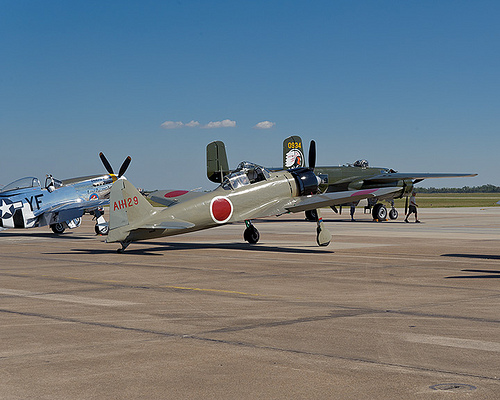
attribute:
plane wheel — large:
[244, 227, 259, 242]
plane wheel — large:
[50, 221, 67, 233]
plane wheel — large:
[94, 224, 108, 235]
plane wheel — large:
[314, 230, 329, 245]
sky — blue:
[127, 59, 167, 95]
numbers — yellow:
[283, 139, 305, 149]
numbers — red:
[102, 191, 144, 220]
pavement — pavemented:
[89, 273, 190, 314]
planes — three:
[33, 125, 370, 252]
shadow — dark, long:
[51, 229, 339, 272]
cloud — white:
[255, 116, 274, 133]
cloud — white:
[204, 117, 235, 132]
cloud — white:
[154, 117, 199, 134]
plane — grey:
[90, 154, 342, 239]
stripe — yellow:
[1, 269, 248, 294]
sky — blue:
[2, 2, 497, 189]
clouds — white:
[155, 116, 276, 133]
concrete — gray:
[1, 205, 498, 398]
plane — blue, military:
[84, 131, 481, 253]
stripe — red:
[346, 187, 377, 202]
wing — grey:
[297, 186, 400, 207]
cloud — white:
[206, 118, 237, 128]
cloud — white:
[158, 117, 196, 132]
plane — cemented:
[1, 148, 137, 232]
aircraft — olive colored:
[83, 137, 355, 268]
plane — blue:
[31, 155, 111, 231]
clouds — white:
[154, 114, 281, 133]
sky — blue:
[3, 2, 498, 169]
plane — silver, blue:
[2, 159, 134, 233]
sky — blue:
[260, 2, 463, 67]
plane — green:
[286, 129, 448, 214]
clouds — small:
[154, 111, 276, 138]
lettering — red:
[107, 189, 145, 213]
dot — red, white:
[207, 189, 237, 229]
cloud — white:
[157, 111, 283, 138]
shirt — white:
[407, 194, 419, 209]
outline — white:
[207, 194, 234, 225]